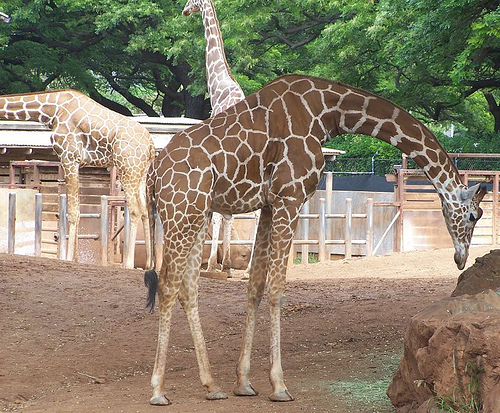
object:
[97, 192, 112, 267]
fence column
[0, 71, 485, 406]
two giraffes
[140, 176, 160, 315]
giraffe tail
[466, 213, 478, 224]
eye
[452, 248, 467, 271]
mouth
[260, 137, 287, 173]
pattern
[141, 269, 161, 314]
hair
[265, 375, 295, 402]
feet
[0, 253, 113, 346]
brown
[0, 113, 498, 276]
pen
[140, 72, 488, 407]
giraffe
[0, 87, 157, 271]
giraffe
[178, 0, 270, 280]
giraffe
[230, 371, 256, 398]
hoof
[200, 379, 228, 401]
hoof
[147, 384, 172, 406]
hoof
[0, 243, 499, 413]
ground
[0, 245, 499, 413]
dirt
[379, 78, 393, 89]
leaves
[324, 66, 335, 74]
leaves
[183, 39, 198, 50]
leaves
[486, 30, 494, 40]
leaves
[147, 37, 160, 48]
leaves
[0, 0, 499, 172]
tree